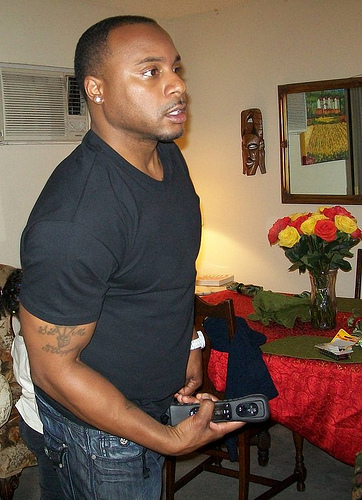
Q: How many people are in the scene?
A: One.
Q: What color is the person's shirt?
A: Black.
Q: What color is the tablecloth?
A: Red.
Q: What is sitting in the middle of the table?
A: Vase.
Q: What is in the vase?
A: Flowers.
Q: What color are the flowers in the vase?
A: Yellow and red.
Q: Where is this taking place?
A: The dining room.